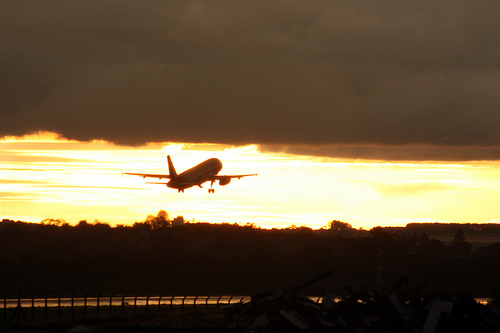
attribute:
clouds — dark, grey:
[0, 0, 499, 160]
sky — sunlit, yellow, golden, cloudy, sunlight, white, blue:
[0, 0, 500, 226]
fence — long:
[0, 293, 255, 327]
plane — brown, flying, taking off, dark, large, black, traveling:
[123, 155, 259, 193]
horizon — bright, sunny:
[1, 136, 498, 226]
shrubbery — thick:
[3, 222, 500, 295]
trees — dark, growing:
[0, 220, 494, 296]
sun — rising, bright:
[122, 145, 398, 225]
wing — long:
[209, 172, 256, 182]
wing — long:
[122, 171, 178, 181]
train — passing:
[406, 223, 499, 234]